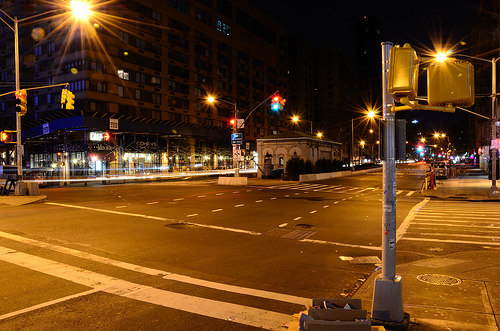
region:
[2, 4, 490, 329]
an empty street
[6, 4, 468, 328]
a very crowded street in the city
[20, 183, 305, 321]
a crosswalk TO WALK across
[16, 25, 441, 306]
a extremely quiet street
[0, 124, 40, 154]
a sign so you do not walk across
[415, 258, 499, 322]
a covered up sewer hole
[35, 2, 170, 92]
street lights in the city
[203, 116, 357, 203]
a little building in the middle of the street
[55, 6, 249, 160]
a big building on the left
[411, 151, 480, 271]
a crosswalk to walk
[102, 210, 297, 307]
an empty road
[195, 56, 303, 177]
street lights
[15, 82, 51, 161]
a red light so you won't go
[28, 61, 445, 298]
a completely empty street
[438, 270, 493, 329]
the sidewalk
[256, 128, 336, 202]
a building in the middle of the street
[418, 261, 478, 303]
a pot hole that is closed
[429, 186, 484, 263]
this is where you can cross the street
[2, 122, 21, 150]
don't walk across the street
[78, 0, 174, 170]
a cool tall building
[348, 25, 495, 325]
cross walk lights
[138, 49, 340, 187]
stop lights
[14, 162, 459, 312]
white lines on the road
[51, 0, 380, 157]
a tall building with lots of windows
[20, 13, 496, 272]
a city at night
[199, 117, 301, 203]
traffic signs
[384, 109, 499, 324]
a sidewalk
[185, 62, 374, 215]
street lights on at night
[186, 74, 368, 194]
street lights blinking red and green lights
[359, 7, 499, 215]
yellow cross walk signs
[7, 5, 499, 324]
an city intersection late at night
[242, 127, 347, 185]
a stone building in the median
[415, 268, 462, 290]
a manhole cover in the street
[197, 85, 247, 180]
a light pole with a sign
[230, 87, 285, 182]
a traffic signal with red and green lights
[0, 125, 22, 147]
a pedestrian signal light at the intersection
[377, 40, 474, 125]
the backs of pedestrian signals on a pole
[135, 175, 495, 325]
crosswalks for pedestrians marked with white lines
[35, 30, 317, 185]
buildings along the thoroughfare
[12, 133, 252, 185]
shops along the sidewalk are closed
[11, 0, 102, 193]
a metal lamp post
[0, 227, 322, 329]
solid white lines on the street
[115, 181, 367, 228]
dotted white lines on the street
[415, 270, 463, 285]
a manhole cover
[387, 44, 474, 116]
a crossing signal for pedestrians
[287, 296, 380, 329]
a box sitting on the sidewalk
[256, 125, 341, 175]
a small building on the median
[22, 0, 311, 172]
a building behind the street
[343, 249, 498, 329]
a paved sidewalk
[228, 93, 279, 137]
two traffic signals